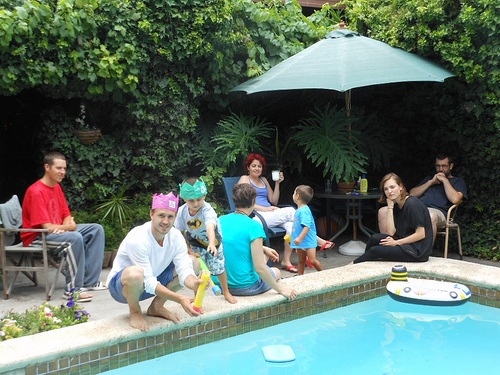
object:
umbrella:
[227, 14, 460, 111]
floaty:
[384, 263, 475, 310]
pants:
[27, 222, 115, 301]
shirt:
[17, 174, 76, 251]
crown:
[149, 186, 180, 213]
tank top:
[245, 173, 274, 211]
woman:
[243, 153, 288, 274]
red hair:
[243, 148, 270, 170]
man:
[419, 150, 468, 237]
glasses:
[435, 161, 451, 168]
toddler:
[291, 181, 321, 286]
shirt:
[290, 205, 323, 254]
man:
[100, 191, 203, 332]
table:
[311, 180, 389, 245]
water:
[311, 299, 471, 367]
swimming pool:
[7, 283, 499, 369]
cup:
[357, 176, 372, 195]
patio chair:
[219, 171, 245, 219]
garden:
[0, 290, 91, 340]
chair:
[1, 193, 61, 293]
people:
[8, 145, 469, 264]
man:
[17, 148, 111, 305]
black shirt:
[409, 170, 469, 214]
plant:
[302, 113, 379, 193]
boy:
[169, 176, 239, 307]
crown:
[174, 181, 213, 202]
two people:
[104, 176, 225, 329]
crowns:
[147, 176, 213, 211]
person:
[358, 171, 439, 263]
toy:
[192, 269, 216, 311]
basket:
[72, 116, 112, 148]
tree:
[6, 5, 156, 99]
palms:
[203, 115, 402, 177]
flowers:
[66, 288, 82, 323]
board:
[261, 336, 300, 363]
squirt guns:
[187, 269, 219, 317]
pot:
[340, 174, 358, 191]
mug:
[270, 168, 283, 183]